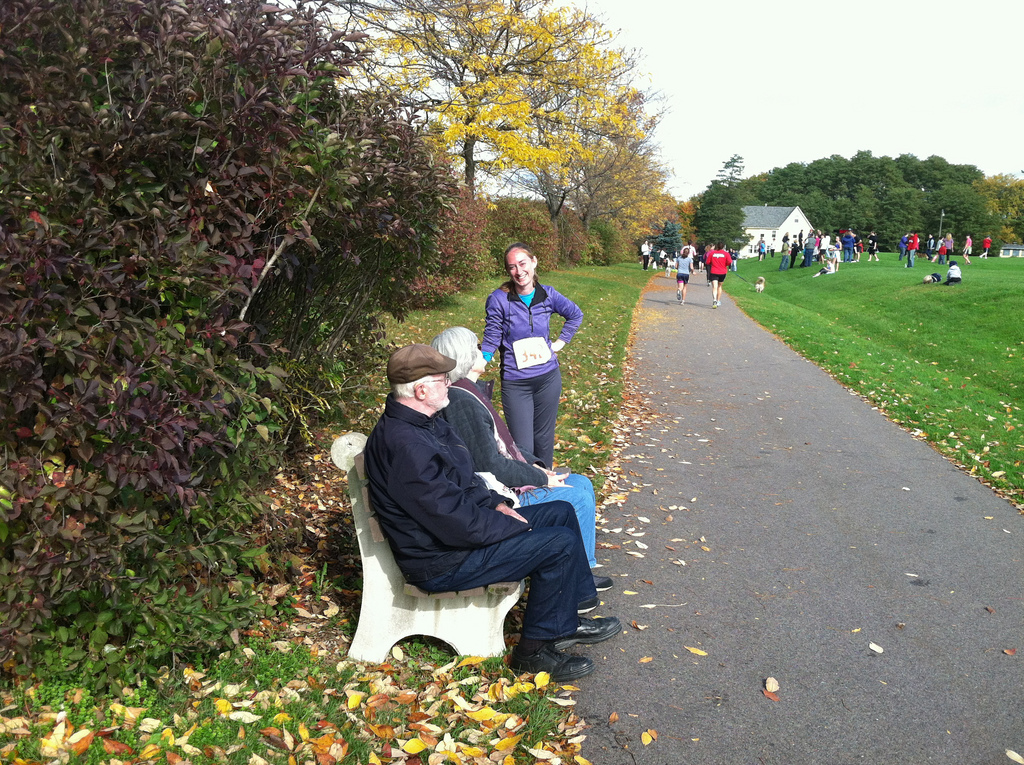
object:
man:
[364, 343, 619, 682]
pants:
[414, 500, 596, 639]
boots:
[511, 645, 595, 682]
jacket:
[363, 392, 533, 584]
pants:
[520, 474, 595, 568]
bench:
[330, 432, 525, 664]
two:
[675, 241, 732, 309]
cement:
[694, 355, 775, 460]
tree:
[372, 0, 630, 196]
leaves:
[645, 286, 664, 292]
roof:
[740, 206, 797, 227]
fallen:
[401, 737, 425, 754]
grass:
[28, 655, 308, 764]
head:
[386, 345, 451, 417]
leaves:
[766, 677, 780, 693]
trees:
[692, 180, 749, 250]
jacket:
[480, 280, 583, 380]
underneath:
[518, 289, 537, 307]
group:
[639, 227, 997, 309]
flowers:
[520, 221, 538, 233]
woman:
[480, 243, 583, 470]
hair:
[430, 326, 478, 383]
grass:
[811, 296, 973, 357]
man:
[707, 242, 732, 309]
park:
[0, 0, 1023, 765]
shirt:
[706, 250, 732, 274]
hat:
[386, 345, 456, 384]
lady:
[430, 327, 612, 592]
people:
[804, 233, 816, 266]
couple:
[365, 325, 620, 681]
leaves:
[345, 690, 361, 709]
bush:
[0, 0, 347, 667]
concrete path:
[564, 264, 1023, 764]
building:
[739, 205, 814, 258]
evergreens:
[885, 187, 925, 253]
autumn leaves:
[442, 101, 561, 166]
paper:
[512, 337, 551, 370]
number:
[511, 337, 551, 369]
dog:
[754, 277, 765, 293]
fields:
[725, 254, 1024, 513]